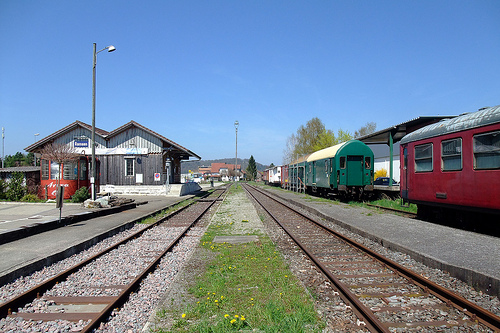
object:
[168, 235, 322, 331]
grass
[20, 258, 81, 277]
rocks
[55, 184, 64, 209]
sign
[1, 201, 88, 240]
parking lot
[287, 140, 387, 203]
train car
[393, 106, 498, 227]
train car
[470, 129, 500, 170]
windows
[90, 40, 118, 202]
light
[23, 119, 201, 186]
building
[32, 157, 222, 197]
platform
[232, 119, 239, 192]
light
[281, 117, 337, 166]
trees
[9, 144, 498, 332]
railroad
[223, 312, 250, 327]
flowers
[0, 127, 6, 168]
lights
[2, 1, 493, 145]
sky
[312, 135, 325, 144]
leaves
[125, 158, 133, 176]
window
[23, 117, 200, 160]
roof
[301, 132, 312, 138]
green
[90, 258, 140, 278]
gravel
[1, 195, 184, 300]
sidewalk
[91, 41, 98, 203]
metal pole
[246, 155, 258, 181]
pine tree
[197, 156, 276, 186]
distance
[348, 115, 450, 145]
awning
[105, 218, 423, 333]
set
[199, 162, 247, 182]
buildings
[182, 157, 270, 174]
mountain range